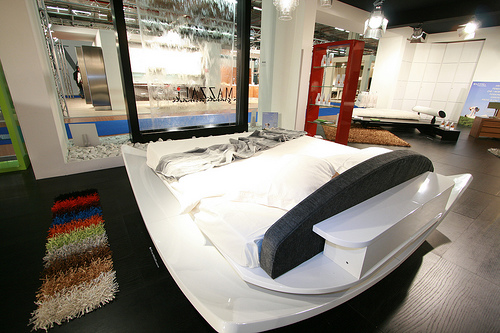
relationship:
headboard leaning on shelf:
[247, 151, 436, 281] [312, 170, 455, 278]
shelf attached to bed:
[312, 170, 455, 278] [118, 129, 473, 332]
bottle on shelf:
[319, 53, 326, 67] [311, 65, 350, 70]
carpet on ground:
[29, 185, 119, 332] [0, 122, 498, 332]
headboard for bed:
[247, 151, 436, 281] [118, 129, 473, 332]